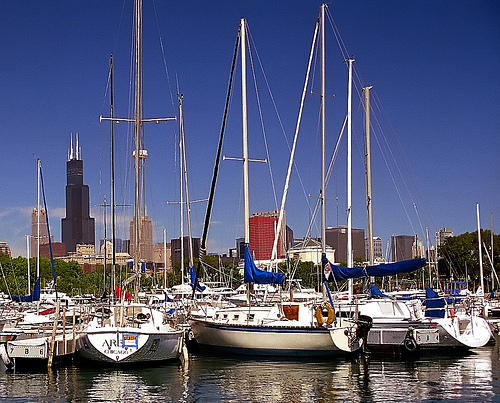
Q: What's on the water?
A: Boats.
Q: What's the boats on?
A: Water.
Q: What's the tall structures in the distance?
A: Buildings.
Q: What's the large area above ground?
A: Sky.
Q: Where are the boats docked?
A: Marina.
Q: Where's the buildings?
A: Behind boats.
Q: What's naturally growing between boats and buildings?
A: Trees.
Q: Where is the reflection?
A: On the water.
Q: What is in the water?
A: White boats.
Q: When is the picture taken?
A: Day time.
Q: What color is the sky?
A: Blue.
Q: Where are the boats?
A: In the water.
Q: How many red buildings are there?
A: One.